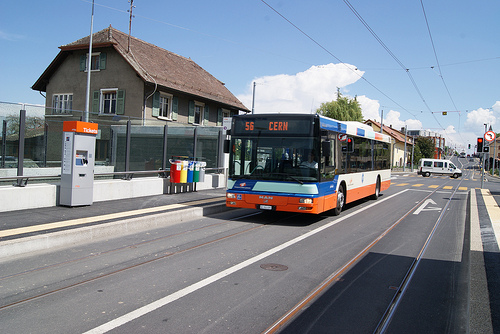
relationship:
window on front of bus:
[229, 135, 321, 183] [227, 112, 392, 216]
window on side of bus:
[372, 139, 392, 171] [224, 101, 391, 212]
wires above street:
[256, 0, 435, 142] [5, 182, 461, 332]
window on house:
[100, 88, 118, 115] [33, 35, 248, 185]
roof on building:
[30, 23, 252, 113] [30, 22, 254, 166]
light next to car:
[476, 137, 486, 153] [417, 157, 462, 178]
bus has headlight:
[219, 107, 413, 224] [222, 190, 243, 202]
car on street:
[411, 155, 465, 177] [7, 159, 476, 323]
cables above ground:
[267, 4, 499, 124] [0, 155, 495, 332]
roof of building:
[65, 7, 255, 108] [29, 24, 253, 181]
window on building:
[86, 54, 101, 71] [30, 23, 252, 165]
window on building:
[51, 92, 71, 112] [30, 23, 252, 165]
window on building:
[101, 89, 118, 112] [30, 23, 252, 165]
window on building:
[157, 92, 171, 117] [30, 23, 252, 165]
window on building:
[192, 101, 200, 122] [30, 23, 252, 165]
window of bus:
[238, 134, 312, 179] [233, 106, 396, 203]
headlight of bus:
[300, 196, 316, 205] [145, 69, 415, 222]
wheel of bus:
[332, 181, 352, 215] [225, 112, 349, 224]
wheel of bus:
[372, 175, 382, 200] [227, 112, 392, 216]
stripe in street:
[455, 183, 467, 191] [7, 159, 476, 323]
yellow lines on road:
[395, 175, 470, 195] [0, 156, 500, 333]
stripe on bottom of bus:
[224, 178, 391, 217] [227, 112, 392, 216]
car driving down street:
[417, 158, 463, 179] [7, 159, 476, 323]